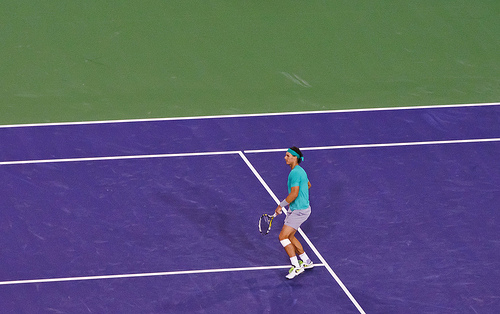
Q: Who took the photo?
A: Fan.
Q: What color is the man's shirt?
A: Teal.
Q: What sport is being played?
A: Tennis.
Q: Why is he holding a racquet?
A: To hit.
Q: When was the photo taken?
A: Afternoon.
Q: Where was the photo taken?
A: Tennis court.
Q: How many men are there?
A: 1.